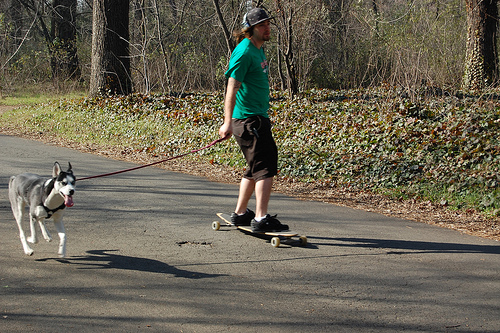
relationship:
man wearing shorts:
[221, 5, 292, 235] [228, 118, 282, 183]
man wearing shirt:
[198, 32, 314, 264] [219, 41, 276, 123]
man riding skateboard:
[208, 2, 313, 259] [214, 195, 307, 262]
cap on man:
[239, 1, 271, 37] [221, 5, 292, 235]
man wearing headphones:
[230, 0, 280, 225] [240, 13, 255, 39]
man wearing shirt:
[217, 10, 289, 233] [224, 31, 271, 122]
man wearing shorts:
[217, 10, 289, 233] [228, 118, 282, 183]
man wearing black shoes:
[190, 0, 334, 213] [198, 188, 330, 265]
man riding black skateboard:
[203, 2, 321, 201] [195, 204, 323, 264]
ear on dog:
[45, 159, 63, 180] [3, 157, 78, 264]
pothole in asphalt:
[175, 233, 218, 261] [3, 134, 496, 331]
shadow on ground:
[129, 252, 195, 302] [330, 222, 420, 314]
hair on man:
[226, 19, 275, 48] [221, 5, 292, 235]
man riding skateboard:
[219, 3, 312, 229] [209, 208, 311, 249]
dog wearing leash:
[7, 160, 84, 266] [73, 128, 232, 188]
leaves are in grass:
[204, 155, 219, 167] [96, 119, 127, 138]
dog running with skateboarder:
[5, 154, 86, 263] [206, 5, 316, 252]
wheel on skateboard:
[270, 237, 280, 247] [268, 226, 308, 248]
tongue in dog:
[63, 195, 73, 207] [6, 160, 79, 260]